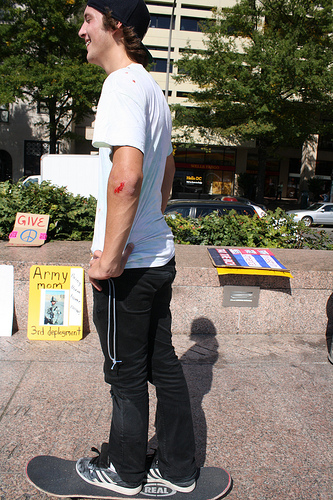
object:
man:
[75, 0, 198, 492]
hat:
[85, 1, 154, 66]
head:
[79, 1, 151, 69]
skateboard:
[25, 454, 232, 500]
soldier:
[45, 295, 62, 325]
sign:
[27, 264, 85, 343]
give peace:
[17, 214, 45, 244]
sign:
[6, 210, 49, 247]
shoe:
[142, 447, 196, 494]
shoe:
[75, 441, 143, 498]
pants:
[93, 256, 199, 487]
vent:
[221, 282, 260, 308]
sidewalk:
[1, 328, 333, 500]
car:
[285, 199, 333, 230]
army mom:
[33, 266, 69, 290]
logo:
[142, 484, 173, 498]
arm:
[104, 81, 147, 244]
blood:
[114, 180, 125, 193]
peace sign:
[20, 228, 37, 242]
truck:
[18, 152, 100, 204]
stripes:
[88, 465, 116, 487]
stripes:
[147, 464, 163, 480]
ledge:
[0, 242, 333, 332]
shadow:
[144, 316, 219, 468]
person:
[276, 180, 283, 201]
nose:
[78, 23, 87, 38]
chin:
[86, 50, 95, 64]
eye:
[85, 13, 94, 23]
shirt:
[90, 62, 176, 269]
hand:
[88, 241, 134, 292]